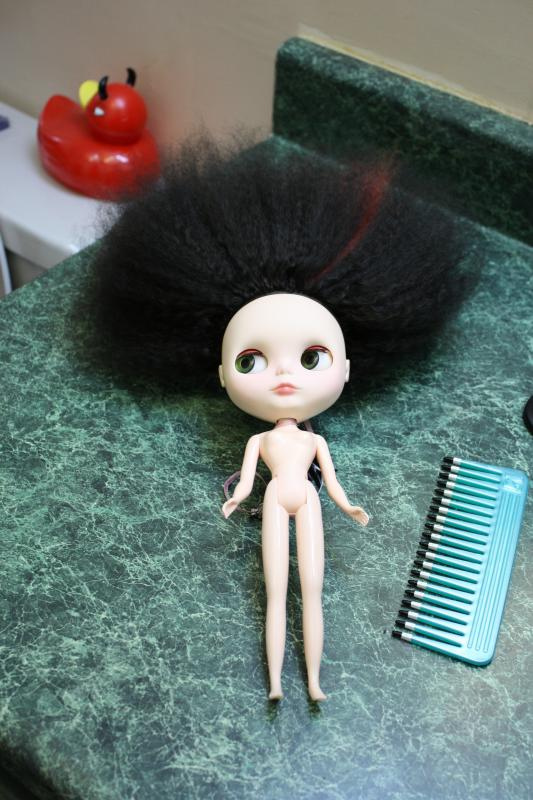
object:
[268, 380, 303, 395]
mouth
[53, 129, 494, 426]
hair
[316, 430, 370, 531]
arm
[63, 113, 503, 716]
doll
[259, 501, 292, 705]
legs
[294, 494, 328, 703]
legs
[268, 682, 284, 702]
feet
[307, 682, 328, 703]
feet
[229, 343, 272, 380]
eyes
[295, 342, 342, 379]
eyes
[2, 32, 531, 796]
counter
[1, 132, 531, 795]
countertop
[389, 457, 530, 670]
comb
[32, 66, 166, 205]
duck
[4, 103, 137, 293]
tank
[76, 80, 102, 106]
beak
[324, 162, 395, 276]
streak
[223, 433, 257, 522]
arm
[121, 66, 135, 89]
horn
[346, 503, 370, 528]
hand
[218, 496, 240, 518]
hand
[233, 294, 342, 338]
forehead